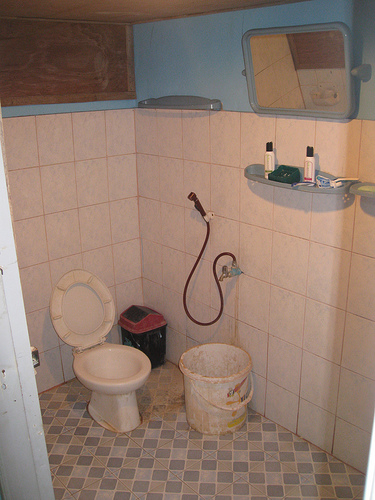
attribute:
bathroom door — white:
[0, 150, 55, 497]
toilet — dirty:
[49, 268, 151, 433]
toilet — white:
[45, 263, 159, 438]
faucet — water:
[218, 262, 242, 281]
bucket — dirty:
[158, 342, 261, 445]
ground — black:
[310, 115, 349, 138]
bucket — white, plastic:
[183, 333, 279, 450]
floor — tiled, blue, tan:
[37, 362, 363, 499]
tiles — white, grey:
[117, 454, 233, 495]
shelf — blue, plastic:
[237, 157, 346, 205]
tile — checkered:
[77, 458, 333, 497]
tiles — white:
[245, 232, 366, 350]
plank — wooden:
[2, 17, 136, 107]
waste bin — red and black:
[118, 299, 171, 370]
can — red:
[115, 298, 174, 368]